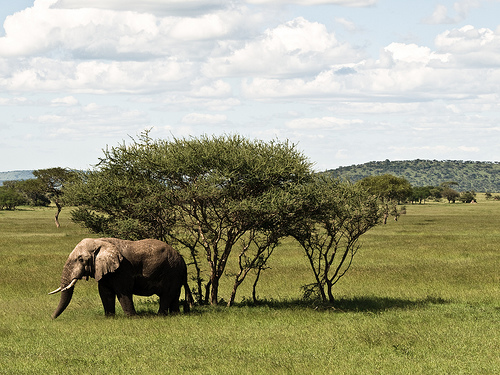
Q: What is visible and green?
A: The grass.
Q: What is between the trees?
A: Green and visible grass.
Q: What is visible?
A: The green grass.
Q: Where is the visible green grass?
A: Between the trees.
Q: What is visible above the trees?
A: The sky.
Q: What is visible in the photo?
A: The sky.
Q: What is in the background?
A: The visible sky.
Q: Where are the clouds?
A: In the visible sky.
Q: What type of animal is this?
A: An elephant.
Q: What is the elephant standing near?
A: Trees.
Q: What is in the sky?
A: Clouds.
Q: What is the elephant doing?
A: Standing.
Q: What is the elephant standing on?
A: Grass.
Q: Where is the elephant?
A: Next to the trees.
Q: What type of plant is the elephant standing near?
A: Trees.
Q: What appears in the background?
A: Mountains.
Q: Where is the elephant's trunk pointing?
A: Down.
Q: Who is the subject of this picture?
A: The elephant.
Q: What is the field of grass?
A: Green.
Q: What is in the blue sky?
A: The cloud.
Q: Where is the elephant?
A: Standing by the trees.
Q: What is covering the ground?
A: Grass.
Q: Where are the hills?
A: In the background behind the plain.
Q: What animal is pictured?
A: Elephant.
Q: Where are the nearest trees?
A: In the center of the photo by the elephant.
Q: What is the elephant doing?
A: Standing.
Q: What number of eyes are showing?
A: One.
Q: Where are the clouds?
A: In the sky.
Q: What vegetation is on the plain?
A: Grass and trees.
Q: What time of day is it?
A: Daytime.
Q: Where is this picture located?
A: Field.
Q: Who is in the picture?
A: Elephant.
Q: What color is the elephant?
A: Gray.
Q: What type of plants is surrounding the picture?
A: Trees.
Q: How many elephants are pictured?
A: One.